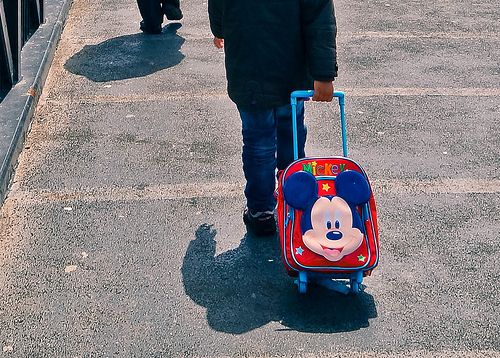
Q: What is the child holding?
A: Suitcase.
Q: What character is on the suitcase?
A: Mickey Mouse.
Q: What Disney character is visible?
A: Mickey.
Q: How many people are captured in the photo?
A: Two.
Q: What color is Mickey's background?
A: Red.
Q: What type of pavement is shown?
A: Asphalt.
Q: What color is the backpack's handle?
A: Blue.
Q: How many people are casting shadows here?
A: Two.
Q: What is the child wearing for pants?
A: Jeans.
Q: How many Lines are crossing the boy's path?
A: Three.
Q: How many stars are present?
A: Three.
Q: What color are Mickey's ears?
A: Purple.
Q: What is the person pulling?
A: Suitcase.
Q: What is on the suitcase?
A: Mickeymouse.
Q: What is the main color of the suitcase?
A: Red.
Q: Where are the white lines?
A: Pavement.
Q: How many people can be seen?
A: Two.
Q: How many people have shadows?
A: Two.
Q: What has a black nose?
A: Mickey.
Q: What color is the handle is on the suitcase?
A: Blue.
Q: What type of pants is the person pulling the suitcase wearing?
A: Jeans.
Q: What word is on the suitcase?
A: Mickey.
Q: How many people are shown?
A: Two.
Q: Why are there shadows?
A: The sun is shining.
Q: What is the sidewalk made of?
A: Concrete.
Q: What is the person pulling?
A: A backpack.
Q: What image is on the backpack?
A: Mickey Mouse.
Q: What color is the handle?
A: Blue.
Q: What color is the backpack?
A: Red.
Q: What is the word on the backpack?
A: Mickey.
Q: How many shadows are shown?
A: Two.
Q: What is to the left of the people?
A: A ledge.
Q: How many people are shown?
A: 2.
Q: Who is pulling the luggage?
A: The person.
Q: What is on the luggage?
A: Mickey mouse.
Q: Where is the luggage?
A: On the street.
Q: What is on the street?
A: Luggage.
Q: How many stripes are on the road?
A: 3.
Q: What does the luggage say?
A: Mickey.